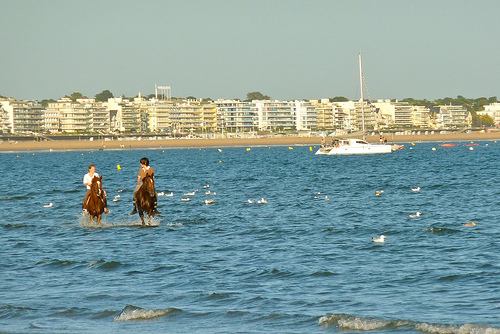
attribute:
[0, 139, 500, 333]
water — blue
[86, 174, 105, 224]
horse — splashing, brown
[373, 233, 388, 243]
bird — floating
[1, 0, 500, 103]
sky — hazy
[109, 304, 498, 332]
waves — small